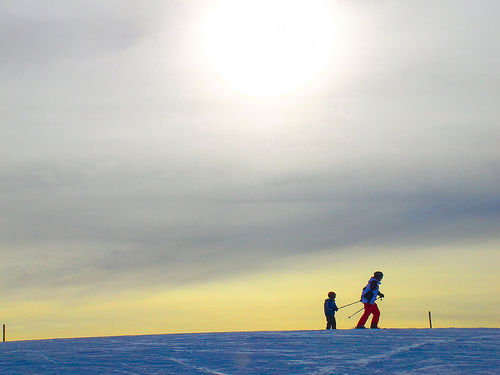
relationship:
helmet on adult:
[373, 271, 383, 281] [353, 268, 384, 329]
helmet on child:
[327, 291, 340, 300] [321, 292, 341, 331]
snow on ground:
[2, 327, 500, 374] [1, 328, 498, 373]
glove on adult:
[356, 272, 386, 332] [355, 271, 384, 329]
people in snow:
[325, 270, 391, 333] [2, 327, 500, 374]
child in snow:
[323, 291, 338, 330] [2, 327, 500, 374]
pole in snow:
[337, 292, 386, 319] [2, 327, 500, 374]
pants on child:
[326, 314, 337, 332] [323, 291, 338, 330]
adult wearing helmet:
[353, 268, 384, 329] [348, 271, 384, 330]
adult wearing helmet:
[355, 271, 384, 329] [373, 271, 383, 281]